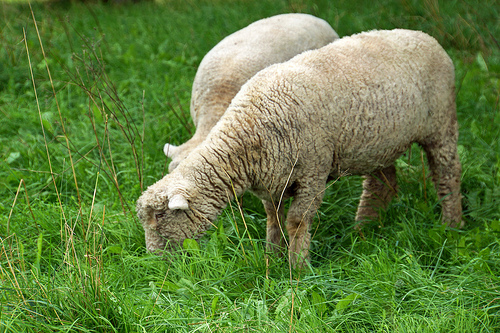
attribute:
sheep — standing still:
[133, 25, 464, 280]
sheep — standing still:
[163, 10, 341, 172]